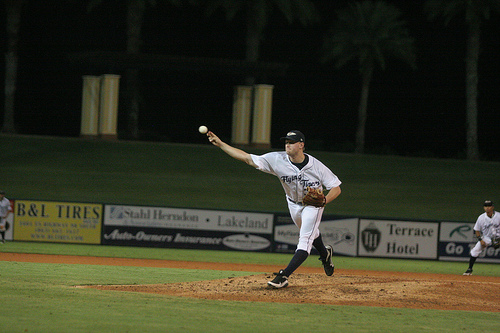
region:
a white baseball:
[200, 122, 211, 133]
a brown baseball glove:
[300, 181, 326, 204]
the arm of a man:
[215, 140, 277, 175]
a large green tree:
[320, 0, 426, 161]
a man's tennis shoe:
[457, 265, 472, 275]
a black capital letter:
[385, 240, 396, 251]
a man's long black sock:
[280, 247, 311, 268]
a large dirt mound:
[90, 257, 497, 310]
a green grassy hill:
[2, 133, 497, 220]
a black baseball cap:
[278, 128, 313, 147]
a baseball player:
[182, 85, 397, 308]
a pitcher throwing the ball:
[157, 71, 364, 291]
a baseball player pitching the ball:
[179, 88, 363, 309]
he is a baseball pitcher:
[177, 90, 362, 290]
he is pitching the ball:
[168, 79, 390, 299]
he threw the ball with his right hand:
[172, 90, 364, 302]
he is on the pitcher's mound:
[177, 93, 372, 310]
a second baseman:
[440, 188, 498, 288]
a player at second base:
[433, 175, 498, 276]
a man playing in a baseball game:
[187, 93, 365, 303]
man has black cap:
[278, 102, 308, 156]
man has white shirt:
[269, 148, 341, 205]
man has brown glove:
[295, 175, 339, 210]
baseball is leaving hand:
[196, 124, 218, 144]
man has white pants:
[280, 195, 341, 269]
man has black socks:
[267, 249, 326, 289]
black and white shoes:
[268, 271, 287, 296]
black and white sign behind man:
[117, 202, 269, 259]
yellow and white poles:
[62, 65, 273, 142]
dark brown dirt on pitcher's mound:
[138, 264, 329, 296]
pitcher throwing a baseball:
[198, 125, 341, 287]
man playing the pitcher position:
[197, 125, 344, 287]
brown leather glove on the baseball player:
[300, 186, 328, 208]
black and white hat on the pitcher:
[281, 130, 306, 144]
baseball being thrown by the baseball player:
[197, 125, 208, 134]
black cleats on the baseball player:
[267, 242, 335, 292]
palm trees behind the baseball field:
[1, 1, 493, 161]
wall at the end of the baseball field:
[0, 198, 499, 263]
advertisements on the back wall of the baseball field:
[0, 194, 499, 262]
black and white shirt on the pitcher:
[250, 151, 341, 204]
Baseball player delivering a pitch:
[195, 120, 342, 290]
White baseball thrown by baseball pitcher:
[192, 122, 209, 133]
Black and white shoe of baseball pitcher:
[265, 266, 290, 287]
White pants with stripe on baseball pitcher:
[282, 197, 322, 250]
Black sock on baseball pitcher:
[282, 247, 305, 277]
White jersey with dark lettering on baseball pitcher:
[250, 150, 340, 208]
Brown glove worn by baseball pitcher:
[300, 185, 326, 210]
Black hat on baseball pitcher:
[277, 128, 304, 143]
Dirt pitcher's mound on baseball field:
[76, 265, 496, 311]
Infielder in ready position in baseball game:
[464, 199, 497, 275]